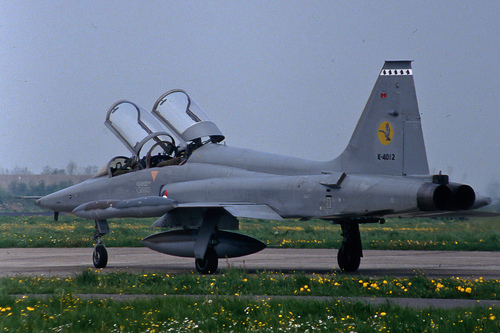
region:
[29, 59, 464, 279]
airplane on the runway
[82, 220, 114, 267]
front wheel is down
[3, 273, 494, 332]
yellow flowers in the grass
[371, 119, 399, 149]
yellow design on the side of the plane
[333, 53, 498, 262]
tail of the plane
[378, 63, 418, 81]
white and black design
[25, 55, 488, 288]
light gray plane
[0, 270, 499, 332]
green grass along the runway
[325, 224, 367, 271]
back wheel is down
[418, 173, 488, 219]
exhaust pipes on the back of the plane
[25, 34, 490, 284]
fighter jet is gray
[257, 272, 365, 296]
the flowers are yellow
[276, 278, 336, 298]
the flowers are yellow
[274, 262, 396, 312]
the flowers are yellow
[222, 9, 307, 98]
grey and cloudy sky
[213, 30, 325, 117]
thick clouds in sky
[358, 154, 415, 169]
black numbers on tail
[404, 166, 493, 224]
black afterburners on tail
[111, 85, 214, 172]
cockpit door is open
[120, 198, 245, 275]
black engine on plane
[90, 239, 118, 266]
black wheel on plane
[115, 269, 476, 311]
green grass with dandelions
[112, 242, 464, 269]
runway is grey and brown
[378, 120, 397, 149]
yellow circle on the tail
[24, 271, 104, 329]
yellow flowers in the grass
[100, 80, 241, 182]
doors open on the plane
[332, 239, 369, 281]
wheel on the back of plane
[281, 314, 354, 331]
white flowers in the grass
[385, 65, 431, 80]
white stripe on the tail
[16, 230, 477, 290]
runway for the plane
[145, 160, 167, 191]
orange triangle under door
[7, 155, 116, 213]
building on side of the plane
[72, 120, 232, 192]
cockpit of the plane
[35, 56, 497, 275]
a plane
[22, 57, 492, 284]
an aircraft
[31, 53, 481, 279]
an army aircraft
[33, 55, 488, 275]
a fighter plane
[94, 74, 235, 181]
two passenger areas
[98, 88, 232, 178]
two glass hatches are open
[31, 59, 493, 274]
no one is on the plane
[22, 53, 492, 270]
the plane is on the runway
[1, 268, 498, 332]
the grass is full of flowers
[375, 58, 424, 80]
a white stripe with black diamonds on the tail of the plane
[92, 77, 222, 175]
two lifted up doors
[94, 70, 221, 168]
two lifted up doors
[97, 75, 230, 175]
two lifted up doors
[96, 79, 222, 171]
two lifted up doors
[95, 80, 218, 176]
two lifted up doors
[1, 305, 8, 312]
yellow flower in grass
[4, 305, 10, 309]
yellow flower in grass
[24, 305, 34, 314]
yellow flower in grass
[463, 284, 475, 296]
yellow flower in grass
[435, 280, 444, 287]
yellow flower in grass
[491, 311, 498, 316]
yellow flower in grass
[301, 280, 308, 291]
yellow flower in grass